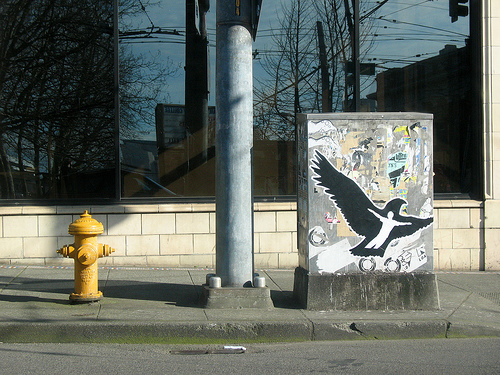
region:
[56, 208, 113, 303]
a yellow fire hydrant on the sidewalk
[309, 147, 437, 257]
a drawing of a bird with a person inside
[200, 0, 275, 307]
a metal traffic pole on the sidewalk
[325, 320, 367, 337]
a large chunk missing from the curb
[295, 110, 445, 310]
a metal box with stickers and artwork on it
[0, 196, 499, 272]
dirty white tiles at the bottom of the building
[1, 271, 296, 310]
shadows cast on the sidewalk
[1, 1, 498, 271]
a building with large windows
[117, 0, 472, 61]
reflections of power lines in the window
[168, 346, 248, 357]
a sewer drain on the street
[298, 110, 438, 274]
gray utility box on a dark base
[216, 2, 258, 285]
gray pole anchored to a concrete base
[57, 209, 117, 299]
yellow fire hydrant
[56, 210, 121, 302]
fire hydrant to the left of pole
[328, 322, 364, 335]
crack visible in curb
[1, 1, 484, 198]
plate glass window behind pole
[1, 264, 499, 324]
gray sidewalk under fire hydrant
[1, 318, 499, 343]
cement curb in front of street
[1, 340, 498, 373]
street is paved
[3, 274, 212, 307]
poles casts shadow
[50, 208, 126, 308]
yellow fire hydrant on sidewalk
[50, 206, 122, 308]
fire hydrant near pole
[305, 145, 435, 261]
bird art on concrete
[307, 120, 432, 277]
graffiti on concrete pillar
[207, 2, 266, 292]
long gray metal pole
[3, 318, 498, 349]
concrete street side curb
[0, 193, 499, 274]
low white stone wall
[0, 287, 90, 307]
shadow of fire hydrant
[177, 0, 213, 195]
reflection of pole in glass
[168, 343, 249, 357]
metal drain in street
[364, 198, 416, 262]
human shape painted on a bird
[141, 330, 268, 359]
green in the street gutter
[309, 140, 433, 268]
outline of a black bird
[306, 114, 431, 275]
painting on an electric transformer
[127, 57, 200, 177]
reflection of a building in a window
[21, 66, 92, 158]
empty black tree branches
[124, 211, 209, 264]
white tile under the windows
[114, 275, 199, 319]
shadows from the street lamp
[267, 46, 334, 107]
reflection of trees on the window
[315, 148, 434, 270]
Bird sticker on board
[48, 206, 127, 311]
yellow fire hydrant on the street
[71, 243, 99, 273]
cap on a fire hydrant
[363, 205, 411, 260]
what sticker on the wall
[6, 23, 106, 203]
reflection of trees on the window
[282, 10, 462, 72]
electric wires in the sky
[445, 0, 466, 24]
light in the reflection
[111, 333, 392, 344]
green paint on the curb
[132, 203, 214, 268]
bricks on the wall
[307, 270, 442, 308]
Concrete base for wall